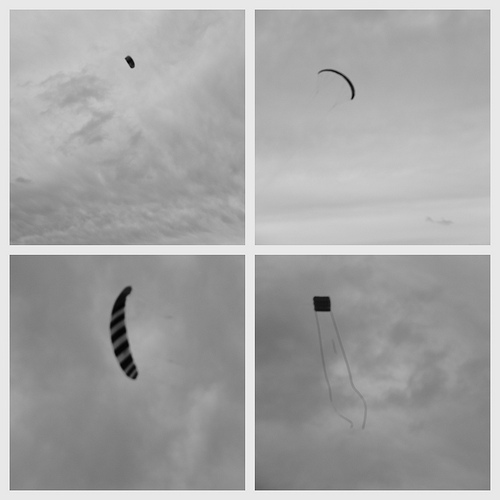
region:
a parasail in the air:
[79, 260, 232, 442]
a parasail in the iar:
[83, 271, 181, 406]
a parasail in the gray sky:
[83, 267, 210, 439]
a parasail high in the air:
[54, 265, 236, 459]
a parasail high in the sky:
[82, 257, 192, 417]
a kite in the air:
[294, 264, 469, 495]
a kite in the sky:
[294, 272, 408, 437]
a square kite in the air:
[269, 271, 402, 466]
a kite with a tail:
[283, 275, 421, 489]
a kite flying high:
[303, 272, 392, 444]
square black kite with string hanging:
[276, 287, 388, 452]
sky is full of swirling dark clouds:
[266, 255, 498, 481]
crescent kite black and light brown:
[106, 266, 158, 394]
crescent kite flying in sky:
[95, 275, 145, 390]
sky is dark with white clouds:
[2, 252, 244, 480]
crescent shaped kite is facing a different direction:
[309, 59, 358, 108]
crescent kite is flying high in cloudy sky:
[246, 1, 491, 244]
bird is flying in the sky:
[261, 134, 353, 172]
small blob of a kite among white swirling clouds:
[39, 41, 218, 201]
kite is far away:
[87, 37, 165, 67]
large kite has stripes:
[95, 277, 155, 416]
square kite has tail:
[295, 286, 409, 418]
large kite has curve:
[307, 58, 391, 125]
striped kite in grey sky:
[80, 278, 182, 410]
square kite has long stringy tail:
[297, 308, 367, 420]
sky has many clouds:
[55, 100, 195, 204]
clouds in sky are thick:
[54, 98, 184, 193]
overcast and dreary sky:
[45, 86, 223, 227]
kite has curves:
[310, 62, 386, 107]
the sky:
[95, 97, 178, 189]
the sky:
[91, 127, 232, 267]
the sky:
[154, 212, 267, 487]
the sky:
[109, 114, 335, 473]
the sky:
[240, 330, 387, 497]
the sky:
[174, 281, 325, 481]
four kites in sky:
[72, 46, 489, 471]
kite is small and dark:
[100, 38, 157, 102]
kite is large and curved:
[306, 56, 355, 116]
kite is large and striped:
[104, 271, 156, 406]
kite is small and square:
[290, 285, 372, 403]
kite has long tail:
[300, 311, 382, 405]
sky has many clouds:
[30, 86, 230, 245]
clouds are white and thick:
[67, 63, 232, 220]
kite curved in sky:
[303, 51, 377, 116]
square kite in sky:
[301, 276, 341, 339]